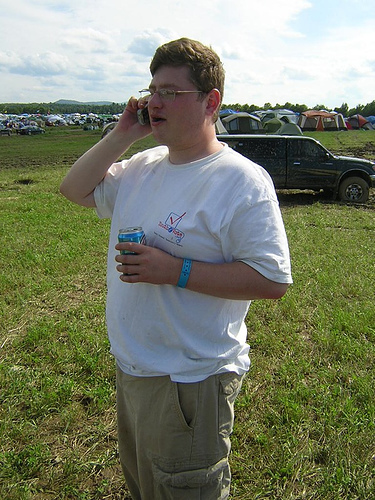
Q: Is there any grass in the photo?
A: Yes, there is grass.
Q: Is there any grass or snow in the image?
A: Yes, there is grass.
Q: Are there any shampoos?
A: No, there are no shampoos.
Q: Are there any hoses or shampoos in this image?
A: No, there are no shampoos or hoses.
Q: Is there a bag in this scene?
A: No, there are no bags.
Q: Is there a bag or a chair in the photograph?
A: No, there are no bags or chairs.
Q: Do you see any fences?
A: No, there are no fences.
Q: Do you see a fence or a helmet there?
A: No, there are no fences or helmets.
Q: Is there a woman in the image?
A: No, there are no women.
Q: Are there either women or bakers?
A: No, there are no women or bakers.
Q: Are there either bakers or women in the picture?
A: No, there are no women or bakers.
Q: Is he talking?
A: Yes, the man is talking.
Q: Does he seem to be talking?
A: Yes, the man is talking.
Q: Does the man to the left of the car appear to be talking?
A: Yes, the man is talking.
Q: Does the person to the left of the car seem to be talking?
A: Yes, the man is talking.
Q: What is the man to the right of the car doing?
A: The man is talking.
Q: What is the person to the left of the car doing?
A: The man is talking.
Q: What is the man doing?
A: The man is talking.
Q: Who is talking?
A: The man is talking.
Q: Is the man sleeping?
A: No, the man is talking.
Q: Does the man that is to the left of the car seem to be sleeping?
A: No, the man is talking.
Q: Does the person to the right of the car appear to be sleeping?
A: No, the man is talking.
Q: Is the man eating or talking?
A: The man is talking.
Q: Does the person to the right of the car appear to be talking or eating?
A: The man is talking.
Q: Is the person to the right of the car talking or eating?
A: The man is talking.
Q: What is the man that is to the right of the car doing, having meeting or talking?
A: The man is talking.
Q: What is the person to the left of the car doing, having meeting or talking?
A: The man is talking.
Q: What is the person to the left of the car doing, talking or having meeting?
A: The man is talking.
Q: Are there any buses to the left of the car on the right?
A: No, there is a man to the left of the car.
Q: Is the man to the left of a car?
A: Yes, the man is to the left of a car.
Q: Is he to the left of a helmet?
A: No, the man is to the left of a car.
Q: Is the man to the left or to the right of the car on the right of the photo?
A: The man is to the left of the car.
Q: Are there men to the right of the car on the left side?
A: Yes, there is a man to the right of the car.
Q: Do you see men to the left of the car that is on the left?
A: No, the man is to the right of the car.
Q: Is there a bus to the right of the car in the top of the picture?
A: No, there is a man to the right of the car.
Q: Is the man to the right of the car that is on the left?
A: Yes, the man is to the right of the car.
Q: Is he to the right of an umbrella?
A: No, the man is to the right of the car.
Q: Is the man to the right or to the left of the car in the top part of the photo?
A: The man is to the right of the car.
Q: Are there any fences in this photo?
A: No, there are no fences.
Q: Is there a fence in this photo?
A: No, there are no fences.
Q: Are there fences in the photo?
A: No, there are no fences.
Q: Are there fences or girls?
A: No, there are no fences or girls.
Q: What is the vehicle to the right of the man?
A: The vehicle is a car.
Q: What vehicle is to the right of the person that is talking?
A: The vehicle is a car.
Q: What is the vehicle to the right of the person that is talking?
A: The vehicle is a car.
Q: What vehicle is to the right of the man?
A: The vehicle is a car.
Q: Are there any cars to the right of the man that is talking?
A: Yes, there is a car to the right of the man.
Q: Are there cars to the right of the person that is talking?
A: Yes, there is a car to the right of the man.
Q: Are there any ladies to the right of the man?
A: No, there is a car to the right of the man.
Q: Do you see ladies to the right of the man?
A: No, there is a car to the right of the man.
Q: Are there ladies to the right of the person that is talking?
A: No, there is a car to the right of the man.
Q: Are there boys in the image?
A: No, there are no boys.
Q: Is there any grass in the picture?
A: Yes, there is grass.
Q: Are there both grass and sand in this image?
A: No, there is grass but no sand.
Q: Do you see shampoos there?
A: No, there are no shampoos.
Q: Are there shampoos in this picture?
A: No, there are no shampoos.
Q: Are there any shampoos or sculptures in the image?
A: No, there are no shampoos or sculptures.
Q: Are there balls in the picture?
A: No, there are no balls.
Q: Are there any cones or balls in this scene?
A: No, there are no balls or cones.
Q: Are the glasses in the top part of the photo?
A: Yes, the glasses are in the top of the image.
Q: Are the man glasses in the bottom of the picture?
A: No, the glasses are in the top of the image.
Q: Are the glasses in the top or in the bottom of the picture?
A: The glasses are in the top of the image.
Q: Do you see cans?
A: Yes, there is a can.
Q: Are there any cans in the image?
A: Yes, there is a can.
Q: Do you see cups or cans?
A: Yes, there is a can.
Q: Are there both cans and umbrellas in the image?
A: No, there is a can but no umbrellas.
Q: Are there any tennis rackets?
A: No, there are no tennis rackets.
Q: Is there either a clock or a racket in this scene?
A: No, there are no rackets or clocks.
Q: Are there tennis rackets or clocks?
A: No, there are no tennis rackets or clocks.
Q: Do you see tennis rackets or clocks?
A: No, there are no tennis rackets or clocks.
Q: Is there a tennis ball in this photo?
A: No, there are no tennis balls.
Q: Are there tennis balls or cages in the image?
A: No, there are no tennis balls or cages.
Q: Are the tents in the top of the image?
A: Yes, the tents are in the top of the image.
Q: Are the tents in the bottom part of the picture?
A: No, the tents are in the top of the image.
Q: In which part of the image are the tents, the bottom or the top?
A: The tents are in the top of the image.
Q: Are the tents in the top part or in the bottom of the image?
A: The tents are in the top of the image.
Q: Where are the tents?
A: The tents are on the grass.